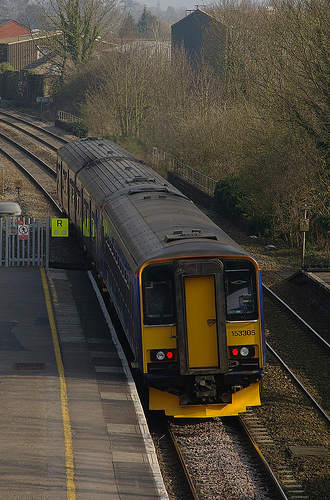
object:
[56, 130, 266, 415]
train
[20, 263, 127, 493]
platform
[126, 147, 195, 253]
roof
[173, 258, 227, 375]
door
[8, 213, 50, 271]
gate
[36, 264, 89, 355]
line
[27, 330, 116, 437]
ground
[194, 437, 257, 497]
rocks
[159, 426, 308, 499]
traintracks